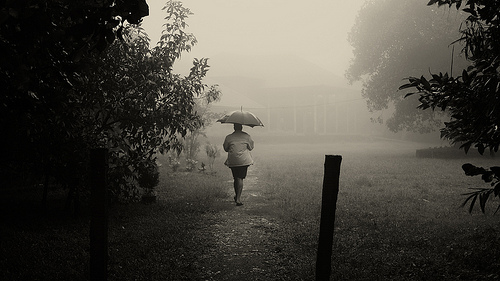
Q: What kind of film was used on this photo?
A: Black and white.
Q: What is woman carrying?
A: Umbrella.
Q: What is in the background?
A: Building.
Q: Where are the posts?
A: Foreground.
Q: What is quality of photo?
A: Black and white.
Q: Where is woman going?
A: To building.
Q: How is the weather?
A: Foggy.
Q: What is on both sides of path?
A: Trees.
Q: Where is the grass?
A: On ground.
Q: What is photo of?
A: Woman walking in rain.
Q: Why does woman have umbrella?
A: It is raining.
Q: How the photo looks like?
A: Black and white.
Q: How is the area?
A: Foggy.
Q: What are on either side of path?
A: Posts.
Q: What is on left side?
A: Trees.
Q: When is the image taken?
A: Walking.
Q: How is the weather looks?
A: Rainy.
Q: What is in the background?
A: Misty air.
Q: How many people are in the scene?
A: One.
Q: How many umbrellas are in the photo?
A: One.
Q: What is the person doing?
A: Walking.